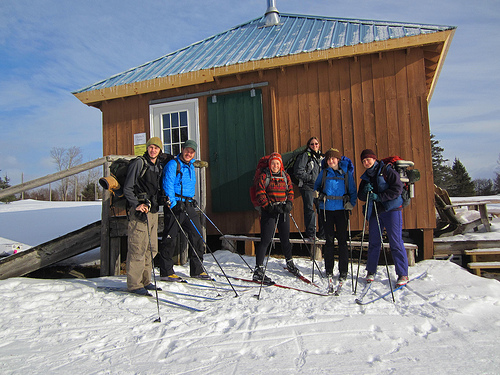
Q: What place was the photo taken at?
A: It was taken at the field.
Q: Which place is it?
A: It is a field.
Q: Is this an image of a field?
A: Yes, it is showing a field.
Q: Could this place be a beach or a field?
A: It is a field.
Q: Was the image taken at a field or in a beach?
A: It was taken at a field.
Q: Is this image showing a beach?
A: No, the picture is showing a field.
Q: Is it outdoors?
A: Yes, it is outdoors.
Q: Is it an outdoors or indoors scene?
A: It is outdoors.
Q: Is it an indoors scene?
A: No, it is outdoors.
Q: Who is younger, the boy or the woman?
A: The boy is younger than the woman.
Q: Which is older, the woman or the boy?
A: The woman is older than the boy.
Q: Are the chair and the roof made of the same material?
A: No, the chair is made of wood and the roof is made of metal.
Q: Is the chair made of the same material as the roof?
A: No, the chair is made of wood and the roof is made of metal.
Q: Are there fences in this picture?
A: No, there are no fences.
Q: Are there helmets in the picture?
A: No, there are no helmets.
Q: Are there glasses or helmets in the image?
A: No, there are no helmets or glasses.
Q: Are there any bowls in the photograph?
A: No, there are no bowls.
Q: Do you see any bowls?
A: No, there are no bowls.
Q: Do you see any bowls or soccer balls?
A: No, there are no bowls or soccer balls.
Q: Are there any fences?
A: No, there are no fences.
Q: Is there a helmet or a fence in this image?
A: No, there are no fences or helmets.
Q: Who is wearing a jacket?
A: The man is wearing a jacket.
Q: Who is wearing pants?
A: The man is wearing pants.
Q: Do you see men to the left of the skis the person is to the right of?
A: Yes, there is a man to the left of the skis.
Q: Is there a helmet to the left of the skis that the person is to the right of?
A: No, there is a man to the left of the skis.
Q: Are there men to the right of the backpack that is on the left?
A: Yes, there is a man to the right of the backpack.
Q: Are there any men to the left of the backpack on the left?
A: No, the man is to the right of the backpack.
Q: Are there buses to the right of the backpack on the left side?
A: No, there is a man to the right of the backpack.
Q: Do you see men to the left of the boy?
A: Yes, there is a man to the left of the boy.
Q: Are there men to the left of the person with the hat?
A: Yes, there is a man to the left of the boy.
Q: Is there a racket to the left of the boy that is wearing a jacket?
A: No, there is a man to the left of the boy.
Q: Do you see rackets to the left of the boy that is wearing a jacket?
A: No, there is a man to the left of the boy.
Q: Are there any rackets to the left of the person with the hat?
A: No, there is a man to the left of the boy.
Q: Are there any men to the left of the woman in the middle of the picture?
A: Yes, there is a man to the left of the woman.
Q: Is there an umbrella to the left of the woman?
A: No, there is a man to the left of the woman.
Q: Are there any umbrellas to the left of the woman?
A: No, there is a man to the left of the woman.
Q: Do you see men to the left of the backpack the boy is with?
A: Yes, there is a man to the left of the backpack.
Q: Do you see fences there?
A: No, there are no fences.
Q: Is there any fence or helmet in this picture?
A: No, there are no fences or helmets.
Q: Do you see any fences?
A: No, there are no fences.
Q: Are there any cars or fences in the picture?
A: No, there are no fences or cars.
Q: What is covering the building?
A: The roof is covering the building.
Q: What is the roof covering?
A: The roof is covering the building.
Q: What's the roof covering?
A: The roof is covering the building.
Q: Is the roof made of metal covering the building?
A: Yes, the roof is covering the building.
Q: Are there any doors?
A: Yes, there is a door.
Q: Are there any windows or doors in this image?
A: Yes, there is a door.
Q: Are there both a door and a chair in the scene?
A: Yes, there are both a door and a chair.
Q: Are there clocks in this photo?
A: No, there are no clocks.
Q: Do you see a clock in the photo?
A: No, there are no clocks.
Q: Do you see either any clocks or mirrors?
A: No, there are no clocks or mirrors.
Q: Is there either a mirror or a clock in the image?
A: No, there are no clocks or mirrors.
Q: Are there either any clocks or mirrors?
A: No, there are no clocks or mirrors.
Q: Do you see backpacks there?
A: Yes, there is a backpack.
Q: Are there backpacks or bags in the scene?
A: Yes, there is a backpack.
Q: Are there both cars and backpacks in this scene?
A: No, there is a backpack but no cars.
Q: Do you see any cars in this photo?
A: No, there are no cars.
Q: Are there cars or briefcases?
A: No, there are no cars or briefcases.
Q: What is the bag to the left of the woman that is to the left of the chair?
A: The bag is a backpack.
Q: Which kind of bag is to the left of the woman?
A: The bag is a backpack.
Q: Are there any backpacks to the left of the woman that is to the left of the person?
A: Yes, there is a backpack to the left of the woman.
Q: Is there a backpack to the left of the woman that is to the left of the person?
A: Yes, there is a backpack to the left of the woman.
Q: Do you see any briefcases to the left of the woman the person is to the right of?
A: No, there is a backpack to the left of the woman.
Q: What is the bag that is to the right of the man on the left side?
A: The bag is a backpack.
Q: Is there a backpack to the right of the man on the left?
A: Yes, there is a backpack to the right of the man.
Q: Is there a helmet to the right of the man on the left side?
A: No, there is a backpack to the right of the man.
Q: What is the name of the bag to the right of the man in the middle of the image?
A: The bag is a backpack.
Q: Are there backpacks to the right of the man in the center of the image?
A: Yes, there is a backpack to the right of the man.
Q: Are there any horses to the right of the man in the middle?
A: No, there is a backpack to the right of the man.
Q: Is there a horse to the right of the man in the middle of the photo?
A: No, there is a backpack to the right of the man.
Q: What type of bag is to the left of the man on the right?
A: The bag is a backpack.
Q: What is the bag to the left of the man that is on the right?
A: The bag is a backpack.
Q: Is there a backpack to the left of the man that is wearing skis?
A: Yes, there is a backpack to the left of the man.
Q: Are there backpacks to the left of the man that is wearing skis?
A: Yes, there is a backpack to the left of the man.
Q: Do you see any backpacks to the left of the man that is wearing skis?
A: Yes, there is a backpack to the left of the man.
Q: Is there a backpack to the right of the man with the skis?
A: No, the backpack is to the left of the man.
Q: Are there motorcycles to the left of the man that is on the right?
A: No, there is a backpack to the left of the man.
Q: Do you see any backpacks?
A: Yes, there is a backpack.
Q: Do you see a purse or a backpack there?
A: Yes, there is a backpack.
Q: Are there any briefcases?
A: No, there are no briefcases.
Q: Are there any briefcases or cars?
A: No, there are no briefcases or cars.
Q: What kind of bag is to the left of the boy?
A: The bag is a backpack.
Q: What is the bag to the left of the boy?
A: The bag is a backpack.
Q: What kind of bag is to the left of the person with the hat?
A: The bag is a backpack.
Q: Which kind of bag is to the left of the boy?
A: The bag is a backpack.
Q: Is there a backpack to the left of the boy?
A: Yes, there is a backpack to the left of the boy.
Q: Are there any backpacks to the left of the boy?
A: Yes, there is a backpack to the left of the boy.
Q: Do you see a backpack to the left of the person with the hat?
A: Yes, there is a backpack to the left of the boy.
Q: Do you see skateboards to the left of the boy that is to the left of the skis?
A: No, there is a backpack to the left of the boy.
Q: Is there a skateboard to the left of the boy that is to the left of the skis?
A: No, there is a backpack to the left of the boy.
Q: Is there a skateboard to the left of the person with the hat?
A: No, there is a backpack to the left of the boy.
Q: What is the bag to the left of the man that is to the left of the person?
A: The bag is a backpack.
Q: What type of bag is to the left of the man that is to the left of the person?
A: The bag is a backpack.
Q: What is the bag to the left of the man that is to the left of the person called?
A: The bag is a backpack.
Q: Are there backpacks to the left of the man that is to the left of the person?
A: Yes, there is a backpack to the left of the man.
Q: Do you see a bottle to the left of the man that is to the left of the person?
A: No, there is a backpack to the left of the man.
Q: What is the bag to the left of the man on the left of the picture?
A: The bag is a backpack.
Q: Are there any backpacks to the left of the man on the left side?
A: Yes, there is a backpack to the left of the man.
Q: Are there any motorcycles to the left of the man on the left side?
A: No, there is a backpack to the left of the man.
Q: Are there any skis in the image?
A: Yes, there are skis.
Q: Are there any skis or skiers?
A: Yes, there are skis.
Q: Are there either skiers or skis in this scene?
A: Yes, there are skis.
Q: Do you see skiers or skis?
A: Yes, there are skis.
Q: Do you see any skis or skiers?
A: Yes, there are skis.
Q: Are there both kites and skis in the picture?
A: No, there are skis but no kites.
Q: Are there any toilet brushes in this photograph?
A: No, there are no toilet brushes.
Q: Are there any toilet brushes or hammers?
A: No, there are no toilet brushes or hammers.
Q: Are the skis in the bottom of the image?
A: Yes, the skis are in the bottom of the image.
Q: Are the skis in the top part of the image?
A: No, the skis are in the bottom of the image.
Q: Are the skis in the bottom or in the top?
A: The skis are in the bottom of the image.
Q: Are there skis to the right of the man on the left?
A: Yes, there are skis to the right of the man.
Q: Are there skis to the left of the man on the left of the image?
A: No, the skis are to the right of the man.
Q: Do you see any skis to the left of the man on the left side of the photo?
A: No, the skis are to the right of the man.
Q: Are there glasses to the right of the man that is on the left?
A: No, there are skis to the right of the man.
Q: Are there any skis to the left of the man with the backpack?
A: Yes, there are skis to the left of the man.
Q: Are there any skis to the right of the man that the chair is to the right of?
A: No, the skis are to the left of the man.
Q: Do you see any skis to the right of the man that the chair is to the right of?
A: No, the skis are to the left of the man.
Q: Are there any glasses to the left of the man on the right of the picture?
A: No, there are skis to the left of the man.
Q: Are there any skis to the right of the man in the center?
A: Yes, there are skis to the right of the man.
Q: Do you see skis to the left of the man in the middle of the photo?
A: No, the skis are to the right of the man.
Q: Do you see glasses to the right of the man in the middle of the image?
A: No, there are skis to the right of the man.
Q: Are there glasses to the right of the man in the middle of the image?
A: No, there are skis to the right of the man.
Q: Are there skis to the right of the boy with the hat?
A: Yes, there are skis to the right of the boy.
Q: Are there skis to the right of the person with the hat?
A: Yes, there are skis to the right of the boy.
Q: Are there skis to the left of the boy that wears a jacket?
A: No, the skis are to the right of the boy.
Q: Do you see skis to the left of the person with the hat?
A: No, the skis are to the right of the boy.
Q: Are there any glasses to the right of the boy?
A: No, there are skis to the right of the boy.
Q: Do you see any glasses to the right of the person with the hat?
A: No, there are skis to the right of the boy.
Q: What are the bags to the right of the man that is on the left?
A: The bags are backpacks.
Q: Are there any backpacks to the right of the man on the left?
A: Yes, there are backpacks to the right of the man.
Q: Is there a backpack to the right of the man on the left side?
A: Yes, there are backpacks to the right of the man.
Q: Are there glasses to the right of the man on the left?
A: No, there are backpacks to the right of the man.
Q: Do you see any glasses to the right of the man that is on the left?
A: No, there are backpacks to the right of the man.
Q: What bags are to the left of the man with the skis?
A: The bags are backpacks.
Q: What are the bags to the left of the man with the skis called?
A: The bags are backpacks.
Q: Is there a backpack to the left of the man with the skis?
A: Yes, there are backpacks to the left of the man.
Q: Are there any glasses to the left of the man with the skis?
A: No, there are backpacks to the left of the man.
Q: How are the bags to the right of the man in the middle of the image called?
A: The bags are backpacks.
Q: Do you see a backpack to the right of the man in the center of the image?
A: Yes, there are backpacks to the right of the man.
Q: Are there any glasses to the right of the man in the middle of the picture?
A: No, there are backpacks to the right of the man.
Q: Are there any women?
A: Yes, there is a woman.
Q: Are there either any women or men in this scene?
A: Yes, there is a woman.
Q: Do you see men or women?
A: Yes, there is a woman.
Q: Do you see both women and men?
A: Yes, there are both a woman and a man.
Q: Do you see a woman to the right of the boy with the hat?
A: Yes, there is a woman to the right of the boy.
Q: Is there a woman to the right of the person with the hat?
A: Yes, there is a woman to the right of the boy.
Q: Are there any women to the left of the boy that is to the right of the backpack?
A: No, the woman is to the right of the boy.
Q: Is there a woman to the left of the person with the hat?
A: No, the woman is to the right of the boy.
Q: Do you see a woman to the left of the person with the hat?
A: No, the woman is to the right of the boy.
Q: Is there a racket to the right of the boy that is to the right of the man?
A: No, there is a woman to the right of the boy.